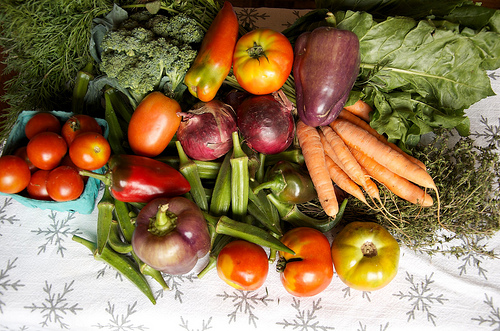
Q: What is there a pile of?
A: Food.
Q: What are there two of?
A: Onions.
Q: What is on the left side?
A: Tomatoes.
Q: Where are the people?
A: None in the photo.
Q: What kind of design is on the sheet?
A: Snowflake.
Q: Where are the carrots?
A: Next to the purple food.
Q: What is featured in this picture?
A: A variety of vegetables.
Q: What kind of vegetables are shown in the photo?
A: A variety of vegetables.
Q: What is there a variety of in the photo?
A: Vegetables.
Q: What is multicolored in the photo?
A: Vegetables.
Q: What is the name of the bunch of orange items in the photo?
A: Carrots.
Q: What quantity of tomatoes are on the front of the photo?
A: Three.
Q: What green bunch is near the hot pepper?
A: Broccoli.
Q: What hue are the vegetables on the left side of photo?
A: Green.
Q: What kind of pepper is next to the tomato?
A: Hot pepper.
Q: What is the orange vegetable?
A: Carrot.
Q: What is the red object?
A: Tomato.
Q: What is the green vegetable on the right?
A: Lettuce.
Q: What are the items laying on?
A: Table.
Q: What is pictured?
A: Broccoli.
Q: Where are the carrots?
A: To the right of the produce.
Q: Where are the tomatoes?
A: To the left of the produce.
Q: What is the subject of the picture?
A: Vegetables and produce.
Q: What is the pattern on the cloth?
A: Snowflake.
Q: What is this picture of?
A: A vegetable patch.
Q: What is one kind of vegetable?
A: Carrots.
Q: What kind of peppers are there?
A: Red peppers.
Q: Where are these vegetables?
A: In a vegetable patch.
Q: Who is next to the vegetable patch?
A: Noone.